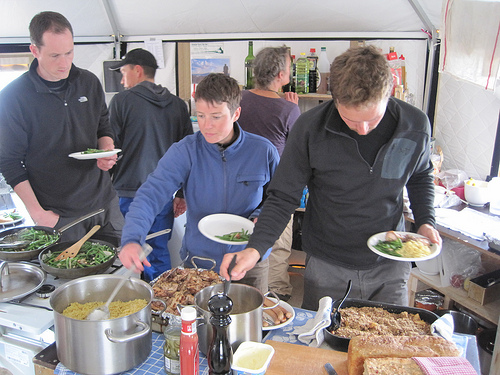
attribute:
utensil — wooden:
[55, 223, 101, 266]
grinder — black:
[208, 290, 231, 374]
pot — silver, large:
[47, 273, 154, 375]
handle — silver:
[104, 322, 152, 342]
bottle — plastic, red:
[178, 305, 201, 374]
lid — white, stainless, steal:
[181, 305, 196, 322]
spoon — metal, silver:
[83, 242, 153, 324]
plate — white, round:
[198, 212, 258, 246]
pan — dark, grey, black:
[1, 207, 108, 262]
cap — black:
[103, 48, 159, 70]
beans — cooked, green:
[0, 229, 58, 250]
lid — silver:
[0, 260, 45, 305]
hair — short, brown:
[29, 12, 74, 52]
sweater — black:
[245, 99, 437, 270]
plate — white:
[367, 231, 441, 264]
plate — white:
[69, 150, 122, 161]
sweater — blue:
[119, 123, 282, 273]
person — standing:
[219, 47, 441, 310]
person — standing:
[119, 74, 278, 296]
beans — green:
[217, 229, 252, 245]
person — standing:
[1, 12, 124, 249]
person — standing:
[105, 49, 192, 283]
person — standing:
[237, 48, 301, 251]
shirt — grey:
[247, 99, 438, 269]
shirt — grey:
[0, 59, 116, 216]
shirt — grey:
[108, 82, 194, 199]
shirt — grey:
[240, 89, 298, 160]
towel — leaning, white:
[288, 297, 333, 349]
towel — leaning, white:
[429, 312, 453, 342]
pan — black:
[317, 299, 445, 353]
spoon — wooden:
[55, 223, 101, 265]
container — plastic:
[228, 339, 276, 374]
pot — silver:
[177, 282, 280, 361]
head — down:
[330, 46, 391, 135]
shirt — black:
[329, 101, 401, 166]